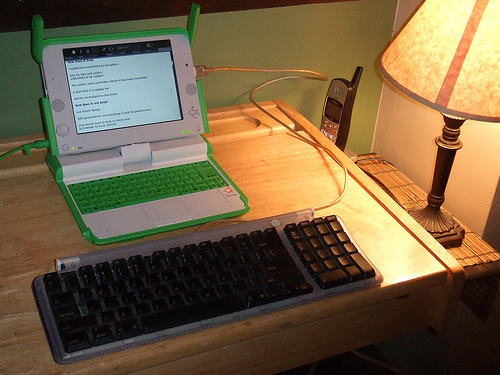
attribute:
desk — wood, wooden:
[1, 99, 466, 374]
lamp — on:
[377, 0, 499, 247]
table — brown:
[351, 153, 500, 320]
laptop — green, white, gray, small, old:
[29, 4, 253, 247]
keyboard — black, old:
[32, 207, 386, 367]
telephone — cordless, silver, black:
[319, 65, 365, 152]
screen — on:
[62, 39, 184, 136]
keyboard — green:
[68, 161, 228, 215]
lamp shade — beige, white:
[377, 0, 499, 124]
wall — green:
[1, 0, 400, 157]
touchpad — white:
[141, 197, 192, 224]